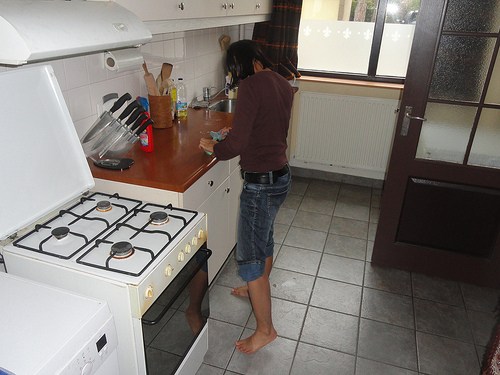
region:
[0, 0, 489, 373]
woman in a kitchen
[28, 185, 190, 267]
stove in a kitchen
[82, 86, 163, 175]
knife block on a counter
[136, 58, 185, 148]
container of cooking tools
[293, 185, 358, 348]
tile on a kitchen floor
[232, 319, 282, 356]
left bare foot of a woman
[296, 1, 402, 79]
window in a kitchen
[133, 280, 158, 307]
knob on a stove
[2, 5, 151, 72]
range of a stove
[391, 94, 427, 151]
handle on a door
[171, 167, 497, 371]
the floor of the kitchen is tiled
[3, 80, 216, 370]
the white stove has an open lid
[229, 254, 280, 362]
the girl is barefoot in the kitchen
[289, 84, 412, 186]
a wall heater is in the kitchen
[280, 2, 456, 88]
a window is in the kitchen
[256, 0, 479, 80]
the window has dark curtains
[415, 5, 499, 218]
frosted glass is on the door's windows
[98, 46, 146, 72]
a paper towel dispenser is on the wall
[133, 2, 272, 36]
cabinets are above the counter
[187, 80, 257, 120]
a stainless steel sink is in the counter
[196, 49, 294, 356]
the person is barefoot in the kitchen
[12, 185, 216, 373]
a gas stove is in the kitchen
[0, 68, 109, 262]
the stove has a white lid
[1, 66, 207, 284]
the lid is open on the stove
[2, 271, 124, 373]
a white dishwasher is in the room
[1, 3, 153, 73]
a range hood is above the stove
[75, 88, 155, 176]
knives are in a see through block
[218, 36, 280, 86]
the person has long black hair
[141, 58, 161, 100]
a rolling pin is on the counter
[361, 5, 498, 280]
an open door is in the kitchen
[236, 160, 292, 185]
Black belt being worn.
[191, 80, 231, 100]
Silver metal sink faucet.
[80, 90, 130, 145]
Large silver kitchen knife.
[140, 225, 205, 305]
Knobs on an oven.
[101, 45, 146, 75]
Roll of paper towels.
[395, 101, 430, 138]
Silver metal door handle.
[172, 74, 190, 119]
Plastic bottle that is almost empty.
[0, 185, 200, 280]
White gas stove top.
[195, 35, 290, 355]
Lady in blue jeans.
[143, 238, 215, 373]
Black glass oven door.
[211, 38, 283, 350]
female in a kitchen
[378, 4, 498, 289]
open door in back of kitchen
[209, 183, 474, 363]
ceramic tile on floor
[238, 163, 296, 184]
belt around waste of female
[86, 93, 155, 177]
rack of knives on counter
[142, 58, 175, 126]
rack of kitchen utensils on counter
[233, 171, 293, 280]
rolled up blue jeans on female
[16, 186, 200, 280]
stove top with four burners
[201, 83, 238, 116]
metal kitchen sink in counter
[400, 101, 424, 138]
silver handle of open door